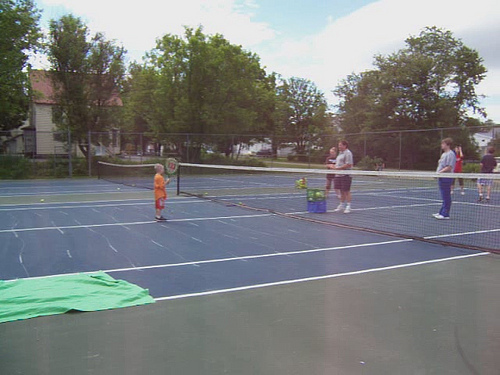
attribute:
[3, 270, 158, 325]
blanket — green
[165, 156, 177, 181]
racket — Wilson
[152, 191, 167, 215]
shorts — red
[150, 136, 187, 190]
racket — tennis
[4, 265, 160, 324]
tarp — green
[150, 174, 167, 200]
shirt — orange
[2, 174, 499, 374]
tennis court — regular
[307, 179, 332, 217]
container — large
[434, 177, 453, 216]
jeans — blue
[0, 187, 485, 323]
court — tennis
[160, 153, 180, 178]
racquet — tennis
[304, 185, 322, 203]
balls — tennis